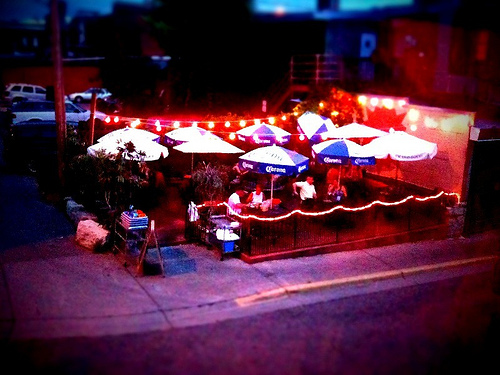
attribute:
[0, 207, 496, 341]
curb — sloped, concrete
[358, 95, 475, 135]
lights — yellow, blurry